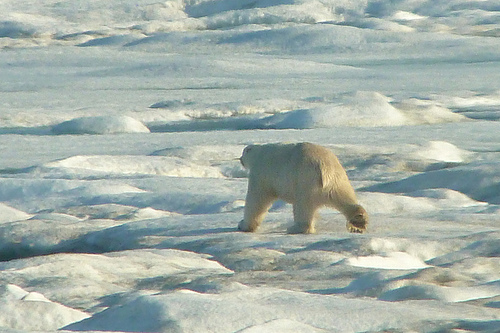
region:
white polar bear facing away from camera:
[231, 138, 378, 239]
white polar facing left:
[227, 135, 374, 242]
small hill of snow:
[51, 110, 155, 140]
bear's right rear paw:
[340, 200, 375, 237]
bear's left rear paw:
[283, 217, 322, 237]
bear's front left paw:
[232, 212, 259, 237]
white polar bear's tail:
[302, 158, 342, 195]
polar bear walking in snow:
[220, 123, 392, 247]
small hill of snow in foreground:
[58, 278, 492, 329]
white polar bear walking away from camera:
[223, 130, 388, 241]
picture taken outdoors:
[36, 25, 496, 318]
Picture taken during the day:
[25, 45, 475, 332]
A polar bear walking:
[54, 34, 479, 325]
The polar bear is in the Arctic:
[87, 57, 419, 280]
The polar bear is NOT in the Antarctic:
[139, 93, 411, 254]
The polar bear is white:
[214, 136, 395, 244]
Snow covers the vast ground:
[91, 77, 374, 267]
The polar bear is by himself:
[215, 125, 382, 260]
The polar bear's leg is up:
[322, 188, 378, 232]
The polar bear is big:
[214, 139, 404, 263]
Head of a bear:
[234, 136, 263, 175]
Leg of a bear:
[283, 191, 318, 250]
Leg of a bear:
[338, 188, 383, 235]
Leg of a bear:
[233, 189, 270, 241]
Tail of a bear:
[310, 153, 335, 200]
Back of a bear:
[245, 140, 344, 163]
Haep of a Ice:
[103, 281, 241, 325]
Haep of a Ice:
[48, 110, 155, 142]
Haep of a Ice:
[45, 145, 207, 192]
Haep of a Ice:
[273, 84, 404, 130]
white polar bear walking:
[211, 123, 381, 258]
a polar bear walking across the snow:
[166, 101, 397, 273]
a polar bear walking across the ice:
[145, 70, 405, 265]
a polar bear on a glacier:
[175, 80, 425, 285]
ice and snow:
[5, 0, 340, 110]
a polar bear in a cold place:
[150, 50, 430, 285]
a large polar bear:
[165, 90, 455, 285]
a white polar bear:
[217, 131, 387, 257]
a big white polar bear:
[191, 110, 436, 265]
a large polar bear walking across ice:
[200, 113, 395, 264]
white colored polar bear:
[235, 144, 366, 238]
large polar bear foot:
[344, 208, 369, 232]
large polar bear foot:
[288, 215, 315, 230]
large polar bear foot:
[236, 218, 256, 231]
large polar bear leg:
[331, 189, 370, 237]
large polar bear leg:
[288, 206, 318, 233]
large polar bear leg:
[238, 187, 266, 232]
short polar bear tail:
[314, 159, 330, 188]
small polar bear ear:
[243, 143, 253, 155]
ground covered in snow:
[0, 1, 498, 326]